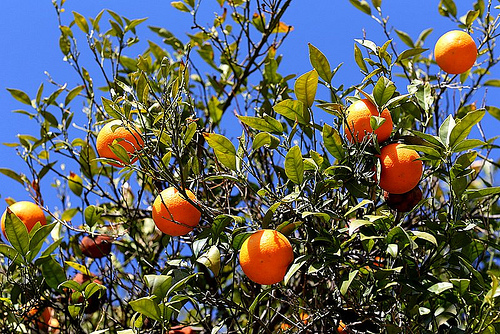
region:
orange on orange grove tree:
[2, 182, 76, 251]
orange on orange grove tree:
[101, 125, 148, 165]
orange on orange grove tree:
[140, 180, 206, 235]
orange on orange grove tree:
[234, 228, 310, 298]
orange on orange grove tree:
[367, 147, 428, 206]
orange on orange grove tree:
[339, 101, 391, 148]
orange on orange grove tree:
[437, 28, 473, 66]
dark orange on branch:
[59, 223, 114, 260]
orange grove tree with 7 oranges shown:
[39, 39, 496, 275]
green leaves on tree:
[284, 162, 336, 194]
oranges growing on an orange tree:
[7, 30, 479, 286]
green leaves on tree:
[142, 47, 307, 171]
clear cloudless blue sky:
[1, 3, 496, 324]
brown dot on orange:
[258, 256, 265, 266]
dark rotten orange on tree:
[79, 229, 110, 259]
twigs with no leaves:
[262, 289, 333, 329]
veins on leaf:
[288, 151, 301, 181]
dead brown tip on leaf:
[69, 167, 76, 178]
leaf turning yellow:
[272, 20, 294, 37]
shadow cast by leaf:
[377, 134, 400, 166]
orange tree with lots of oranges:
[0, 0, 499, 332]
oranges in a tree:
[0, 25, 475, 282]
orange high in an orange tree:
[433, 29, 476, 76]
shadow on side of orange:
[238, 229, 293, 287]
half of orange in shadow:
[433, 40, 478, 75]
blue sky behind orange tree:
[0, 1, 497, 247]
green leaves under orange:
[0, 208, 54, 267]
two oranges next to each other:
[337, 96, 423, 194]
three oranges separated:
[87, 115, 293, 288]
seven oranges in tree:
[0, 29, 478, 285]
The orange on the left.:
[5, 193, 44, 244]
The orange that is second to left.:
[81, 109, 146, 169]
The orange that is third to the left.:
[143, 179, 205, 242]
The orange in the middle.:
[235, 220, 292, 291]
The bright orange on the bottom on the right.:
[372, 142, 424, 192]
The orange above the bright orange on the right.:
[341, 96, 400, 150]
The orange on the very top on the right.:
[422, 28, 477, 75]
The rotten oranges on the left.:
[63, 228, 115, 310]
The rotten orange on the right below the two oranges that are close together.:
[376, 180, 426, 221]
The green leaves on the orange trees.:
[3, 7, 496, 332]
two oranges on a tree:
[338, 75, 423, 212]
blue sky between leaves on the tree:
[290, 45, 348, 107]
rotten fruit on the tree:
[74, 225, 122, 258]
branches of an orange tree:
[187, 29, 257, 136]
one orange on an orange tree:
[7, 195, 52, 253]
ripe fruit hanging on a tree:
[218, 221, 307, 291]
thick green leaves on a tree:
[381, 232, 458, 296]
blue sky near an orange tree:
[6, 18, 48, 60]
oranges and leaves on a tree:
[96, 120, 237, 232]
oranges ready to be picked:
[153, 187, 302, 282]